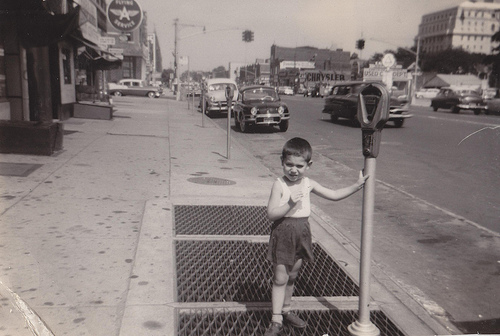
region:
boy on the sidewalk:
[214, 111, 370, 323]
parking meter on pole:
[309, 23, 389, 334]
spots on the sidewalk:
[39, 240, 130, 321]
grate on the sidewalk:
[179, 210, 259, 301]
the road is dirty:
[408, 212, 490, 309]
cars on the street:
[157, 55, 329, 122]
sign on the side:
[130, 18, 142, 28]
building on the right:
[436, 11, 496, 67]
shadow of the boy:
[232, 283, 259, 314]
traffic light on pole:
[168, 2, 271, 55]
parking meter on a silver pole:
[336, 76, 396, 335]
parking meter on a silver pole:
[217, 80, 240, 163]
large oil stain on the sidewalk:
[184, 169, 236, 191]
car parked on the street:
[225, 82, 299, 134]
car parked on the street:
[198, 74, 246, 116]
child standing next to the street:
[247, 132, 369, 334]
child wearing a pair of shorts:
[234, 138, 374, 335]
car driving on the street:
[317, 80, 407, 130]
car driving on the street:
[422, 81, 491, 119]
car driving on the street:
[101, 72, 167, 101]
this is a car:
[230, 78, 285, 135]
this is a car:
[199, 58, 246, 128]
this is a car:
[316, 60, 414, 157]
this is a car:
[423, 62, 485, 132]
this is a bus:
[299, 60, 354, 102]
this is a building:
[409, 6, 491, 79]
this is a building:
[0, 0, 120, 140]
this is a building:
[99, 3, 176, 103]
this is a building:
[269, 30, 350, 89]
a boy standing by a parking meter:
[28, 7, 461, 334]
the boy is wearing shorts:
[239, 101, 363, 334]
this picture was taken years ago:
[41, 4, 493, 309]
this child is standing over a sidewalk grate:
[175, 131, 356, 332]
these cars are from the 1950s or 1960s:
[188, 63, 303, 142]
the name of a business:
[87, 1, 149, 73]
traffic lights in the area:
[201, 8, 422, 63]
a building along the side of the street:
[401, 6, 494, 86]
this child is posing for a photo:
[242, 130, 459, 334]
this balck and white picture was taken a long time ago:
[10, 14, 427, 335]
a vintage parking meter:
[351, 80, 391, 332]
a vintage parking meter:
[222, 82, 235, 161]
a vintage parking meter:
[200, 80, 205, 125]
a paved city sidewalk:
[0, 87, 450, 329]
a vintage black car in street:
[230, 80, 290, 130]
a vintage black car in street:
[321, 80, 408, 126]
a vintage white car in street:
[200, 75, 237, 115]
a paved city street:
[181, 83, 496, 333]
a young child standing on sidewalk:
[261, 136, 368, 334]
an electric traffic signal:
[240, 27, 255, 44]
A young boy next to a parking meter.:
[266, 81, 395, 334]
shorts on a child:
[268, 214, 318, 270]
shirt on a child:
[273, 168, 313, 215]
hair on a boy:
[281, 134, 319, 177]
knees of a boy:
[270, 268, 301, 292]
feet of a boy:
[263, 308, 306, 335]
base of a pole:
[342, 313, 383, 333]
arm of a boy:
[313, 165, 355, 204]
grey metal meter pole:
[357, 155, 379, 317]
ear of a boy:
[303, 154, 314, 170]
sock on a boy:
[272, 303, 286, 321]